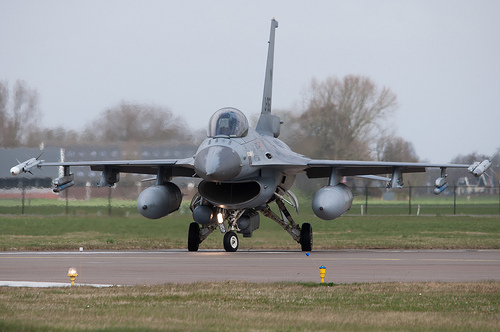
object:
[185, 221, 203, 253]
wheels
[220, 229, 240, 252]
wheels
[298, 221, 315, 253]
wheels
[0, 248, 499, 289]
runway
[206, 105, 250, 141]
cockpit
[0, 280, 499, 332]
grass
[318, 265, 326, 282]
post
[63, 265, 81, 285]
post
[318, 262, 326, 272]
light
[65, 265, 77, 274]
light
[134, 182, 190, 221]
engine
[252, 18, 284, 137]
part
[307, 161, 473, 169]
edge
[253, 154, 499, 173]
wing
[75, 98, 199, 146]
tree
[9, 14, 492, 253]
plane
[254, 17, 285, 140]
tail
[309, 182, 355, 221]
engine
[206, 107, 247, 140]
window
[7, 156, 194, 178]
plane wing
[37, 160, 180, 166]
edge